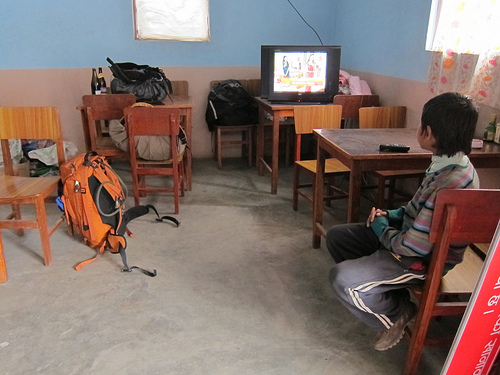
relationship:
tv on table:
[260, 43, 341, 104] [253, 97, 369, 195]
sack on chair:
[104, 118, 192, 162] [122, 105, 184, 213]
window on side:
[422, 1, 499, 133] [341, 4, 499, 256]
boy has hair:
[325, 92, 479, 349] [419, 93, 478, 162]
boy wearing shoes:
[325, 92, 479, 349] [370, 295, 418, 357]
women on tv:
[283, 56, 321, 88] [260, 43, 341, 104]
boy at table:
[325, 92, 479, 349] [312, 126, 498, 250]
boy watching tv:
[325, 92, 479, 349] [260, 43, 341, 104]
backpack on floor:
[62, 150, 162, 276] [2, 156, 500, 373]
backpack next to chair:
[62, 150, 162, 276] [5, 108, 66, 268]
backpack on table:
[104, 55, 174, 103] [76, 91, 195, 193]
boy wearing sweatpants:
[325, 92, 479, 349] [318, 223, 448, 338]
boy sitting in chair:
[325, 92, 479, 349] [401, 188, 494, 374]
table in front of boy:
[312, 126, 498, 250] [325, 92, 479, 349]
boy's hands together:
[325, 92, 479, 349] [365, 207, 388, 231]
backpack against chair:
[62, 150, 162, 276] [5, 108, 66, 268]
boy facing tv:
[325, 92, 479, 349] [260, 43, 341, 104]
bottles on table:
[88, 65, 108, 95] [76, 91, 195, 193]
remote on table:
[377, 142, 412, 155] [312, 126, 498, 250]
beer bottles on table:
[88, 65, 108, 95] [76, 91, 195, 193]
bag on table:
[104, 55, 174, 103] [76, 91, 195, 193]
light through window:
[430, 6, 498, 72] [422, 1, 499, 133]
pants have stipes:
[318, 223, 448, 338] [347, 272, 427, 331]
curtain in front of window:
[422, 1, 499, 133] [427, 2, 497, 150]